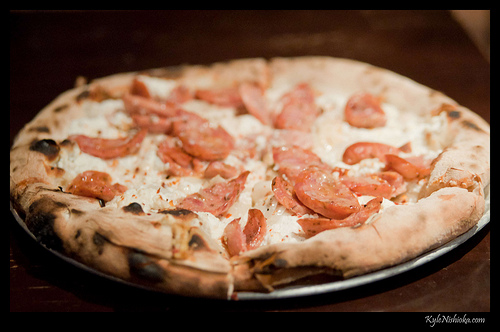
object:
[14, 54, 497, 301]
pizza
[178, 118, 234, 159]
pepperoni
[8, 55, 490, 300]
dish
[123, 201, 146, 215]
spots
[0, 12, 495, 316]
table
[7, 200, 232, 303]
edge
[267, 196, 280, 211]
bubble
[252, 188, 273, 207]
cheese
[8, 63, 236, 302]
crust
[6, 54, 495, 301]
crust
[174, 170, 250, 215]
pepperoni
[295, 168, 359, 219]
pepperoni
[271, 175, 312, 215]
pepperoni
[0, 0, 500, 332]
background